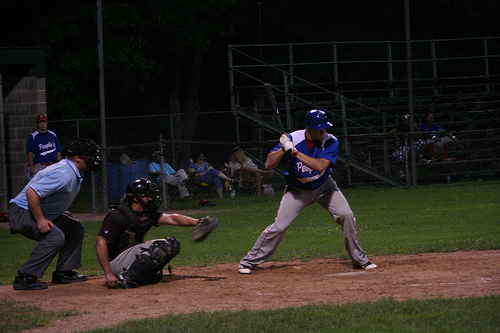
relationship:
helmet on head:
[304, 106, 331, 133] [302, 106, 335, 140]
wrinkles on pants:
[344, 234, 367, 264] [239, 176, 372, 268]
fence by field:
[88, 127, 498, 209] [0, 179, 499, 331]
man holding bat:
[237, 109, 378, 276] [261, 78, 299, 167]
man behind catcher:
[6, 137, 106, 291] [93, 165, 218, 291]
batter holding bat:
[235, 79, 376, 276] [264, 80, 293, 153]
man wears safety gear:
[95, 176, 219, 290] [116, 236, 185, 288]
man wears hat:
[24, 110, 64, 174] [33, 109, 50, 122]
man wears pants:
[237, 109, 378, 276] [244, 175, 367, 262]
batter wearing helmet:
[237, 108, 379, 275] [293, 102, 350, 142]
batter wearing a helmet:
[237, 108, 379, 275] [300, 101, 332, 132]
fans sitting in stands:
[386, 100, 462, 176] [270, 79, 497, 190]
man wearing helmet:
[267, 97, 385, 289] [302, 104, 334, 131]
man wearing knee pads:
[96, 172, 221, 291] [141, 233, 185, 269]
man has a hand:
[4, 132, 103, 289] [34, 217, 54, 235]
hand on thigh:
[34, 217, 54, 235] [18, 214, 58, 235]